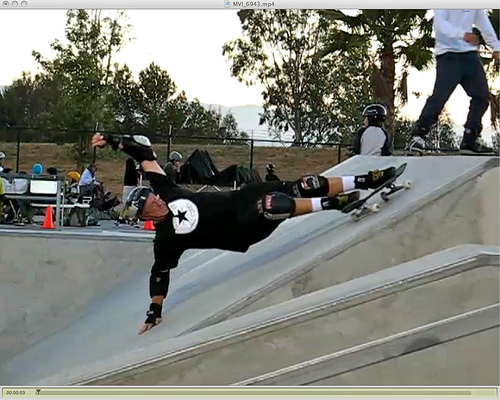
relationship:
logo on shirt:
[165, 197, 201, 239] [141, 167, 245, 275]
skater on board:
[91, 129, 413, 337] [341, 161, 415, 222]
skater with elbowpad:
[91, 129, 413, 337] [121, 131, 157, 164]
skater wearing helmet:
[91, 129, 413, 337] [124, 184, 155, 224]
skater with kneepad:
[91, 129, 413, 337] [257, 192, 295, 220]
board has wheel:
[341, 161, 415, 222] [400, 177, 413, 191]